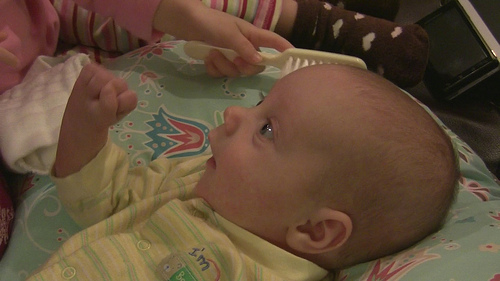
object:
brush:
[185, 39, 368, 76]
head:
[195, 61, 457, 269]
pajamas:
[26, 140, 331, 281]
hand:
[70, 62, 138, 129]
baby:
[26, 63, 456, 281]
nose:
[224, 106, 248, 136]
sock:
[289, 0, 427, 89]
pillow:
[1, 39, 498, 281]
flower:
[144, 103, 213, 162]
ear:
[285, 208, 354, 255]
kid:
[0, 0, 432, 94]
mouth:
[204, 135, 217, 170]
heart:
[363, 33, 376, 51]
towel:
[0, 51, 94, 177]